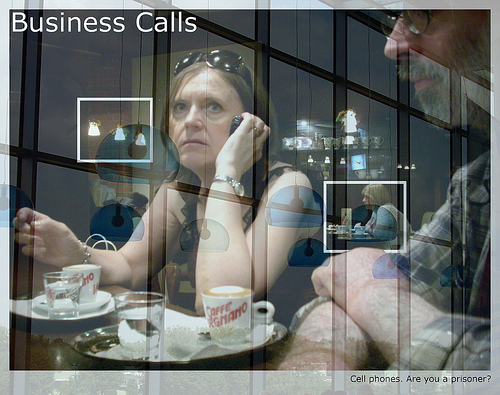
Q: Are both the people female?
A: No, they are both male and female.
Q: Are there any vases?
A: No, there are no vases.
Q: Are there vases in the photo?
A: No, there are no vases.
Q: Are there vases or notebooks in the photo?
A: No, there are no vases or notebooks.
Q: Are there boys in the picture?
A: No, there are no boys.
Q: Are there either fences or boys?
A: No, there are no boys or fences.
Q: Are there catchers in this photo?
A: No, there are no catchers.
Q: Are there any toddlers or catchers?
A: No, there are no catchers or toddlers.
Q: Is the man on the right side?
A: Yes, the man is on the right of the image.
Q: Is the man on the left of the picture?
A: No, the man is on the right of the image.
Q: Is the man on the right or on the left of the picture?
A: The man is on the right of the image.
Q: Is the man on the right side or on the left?
A: The man is on the right of the image.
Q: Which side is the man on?
A: The man is on the right of the image.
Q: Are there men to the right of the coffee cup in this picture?
A: Yes, there is a man to the right of the coffee cup.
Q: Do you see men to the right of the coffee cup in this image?
A: Yes, there is a man to the right of the coffee cup.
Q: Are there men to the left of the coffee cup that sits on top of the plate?
A: No, the man is to the right of the coffee cup.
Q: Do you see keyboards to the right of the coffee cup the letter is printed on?
A: No, there is a man to the right of the coffee cup.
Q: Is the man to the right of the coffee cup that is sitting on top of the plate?
A: Yes, the man is to the right of the coffee cup.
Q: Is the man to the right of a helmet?
A: No, the man is to the right of the coffee cup.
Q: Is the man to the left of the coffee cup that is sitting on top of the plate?
A: No, the man is to the right of the coffee cup.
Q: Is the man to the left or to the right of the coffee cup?
A: The man is to the right of the coffee cup.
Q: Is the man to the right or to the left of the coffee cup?
A: The man is to the right of the coffee cup.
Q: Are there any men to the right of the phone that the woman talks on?
A: Yes, there is a man to the right of the phone.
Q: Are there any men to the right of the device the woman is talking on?
A: Yes, there is a man to the right of the phone.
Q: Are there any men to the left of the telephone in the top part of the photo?
A: No, the man is to the right of the telephone.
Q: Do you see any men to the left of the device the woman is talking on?
A: No, the man is to the right of the telephone.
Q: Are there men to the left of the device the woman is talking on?
A: No, the man is to the right of the telephone.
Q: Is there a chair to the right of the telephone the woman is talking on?
A: No, there is a man to the right of the telephone.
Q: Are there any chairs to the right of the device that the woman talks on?
A: No, there is a man to the right of the telephone.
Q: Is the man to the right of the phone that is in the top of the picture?
A: Yes, the man is to the right of the telephone.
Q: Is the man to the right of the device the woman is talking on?
A: Yes, the man is to the right of the telephone.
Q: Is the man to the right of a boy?
A: No, the man is to the right of the telephone.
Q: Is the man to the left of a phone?
A: No, the man is to the right of a phone.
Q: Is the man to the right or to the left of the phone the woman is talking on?
A: The man is to the right of the telephone.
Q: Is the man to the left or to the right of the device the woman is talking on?
A: The man is to the right of the telephone.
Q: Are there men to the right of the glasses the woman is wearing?
A: Yes, there is a man to the right of the glasses.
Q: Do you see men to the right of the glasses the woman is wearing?
A: Yes, there is a man to the right of the glasses.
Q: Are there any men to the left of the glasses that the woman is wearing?
A: No, the man is to the right of the glasses.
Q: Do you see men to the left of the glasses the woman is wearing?
A: No, the man is to the right of the glasses.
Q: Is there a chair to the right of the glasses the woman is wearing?
A: No, there is a man to the right of the glasses.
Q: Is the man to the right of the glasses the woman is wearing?
A: Yes, the man is to the right of the glasses.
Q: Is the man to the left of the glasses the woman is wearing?
A: No, the man is to the right of the glasses.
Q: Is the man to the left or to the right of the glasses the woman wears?
A: The man is to the right of the glasses.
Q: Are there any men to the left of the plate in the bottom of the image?
A: No, the man is to the right of the plate.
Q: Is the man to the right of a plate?
A: Yes, the man is to the right of a plate.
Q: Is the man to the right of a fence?
A: No, the man is to the right of a plate.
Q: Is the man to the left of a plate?
A: No, the man is to the right of a plate.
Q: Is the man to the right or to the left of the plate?
A: The man is to the right of the plate.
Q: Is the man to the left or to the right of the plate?
A: The man is to the right of the plate.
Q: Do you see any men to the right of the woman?
A: Yes, there is a man to the right of the woman.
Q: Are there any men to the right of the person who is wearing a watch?
A: Yes, there is a man to the right of the woman.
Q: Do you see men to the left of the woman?
A: No, the man is to the right of the woman.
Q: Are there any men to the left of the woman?
A: No, the man is to the right of the woman.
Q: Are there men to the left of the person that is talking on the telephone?
A: No, the man is to the right of the woman.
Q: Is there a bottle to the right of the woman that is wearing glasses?
A: No, there is a man to the right of the woman.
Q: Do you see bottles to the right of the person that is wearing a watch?
A: No, there is a man to the right of the woman.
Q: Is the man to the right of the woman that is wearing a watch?
A: Yes, the man is to the right of the woman.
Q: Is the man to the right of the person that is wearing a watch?
A: Yes, the man is to the right of the woman.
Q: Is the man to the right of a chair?
A: No, the man is to the right of the woman.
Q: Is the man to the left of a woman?
A: No, the man is to the right of a woman.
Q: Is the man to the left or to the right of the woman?
A: The man is to the right of the woman.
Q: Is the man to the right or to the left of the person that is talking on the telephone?
A: The man is to the right of the woman.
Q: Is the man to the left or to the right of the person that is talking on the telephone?
A: The man is to the right of the woman.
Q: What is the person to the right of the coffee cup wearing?
A: The man is wearing glasses.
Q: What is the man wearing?
A: The man is wearing glasses.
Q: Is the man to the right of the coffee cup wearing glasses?
A: Yes, the man is wearing glasses.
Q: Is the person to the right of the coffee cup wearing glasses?
A: Yes, the man is wearing glasses.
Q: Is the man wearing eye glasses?
A: No, the man is wearing glasses.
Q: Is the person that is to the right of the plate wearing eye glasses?
A: No, the man is wearing glasses.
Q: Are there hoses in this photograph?
A: No, there are no hoses.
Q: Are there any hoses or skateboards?
A: No, there are no hoses or skateboards.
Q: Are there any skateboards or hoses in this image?
A: No, there are no hoses or skateboards.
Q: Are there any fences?
A: No, there are no fences.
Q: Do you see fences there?
A: No, there are no fences.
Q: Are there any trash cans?
A: No, there are no trash cans.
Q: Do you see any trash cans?
A: No, there are no trash cans.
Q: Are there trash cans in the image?
A: No, there are no trash cans.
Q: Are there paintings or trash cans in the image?
A: No, there are no trash cans or paintings.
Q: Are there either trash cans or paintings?
A: No, there are no trash cans or paintings.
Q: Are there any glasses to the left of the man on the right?
A: Yes, there are glasses to the left of the man.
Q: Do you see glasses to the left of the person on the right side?
A: Yes, there are glasses to the left of the man.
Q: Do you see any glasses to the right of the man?
A: No, the glasses are to the left of the man.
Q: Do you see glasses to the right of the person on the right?
A: No, the glasses are to the left of the man.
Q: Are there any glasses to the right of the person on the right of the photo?
A: No, the glasses are to the left of the man.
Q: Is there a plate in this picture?
A: Yes, there is a plate.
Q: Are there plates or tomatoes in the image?
A: Yes, there is a plate.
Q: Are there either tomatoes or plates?
A: Yes, there is a plate.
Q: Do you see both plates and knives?
A: No, there is a plate but no knives.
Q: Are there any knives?
A: No, there are no knives.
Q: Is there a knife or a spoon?
A: No, there are no knives or spoons.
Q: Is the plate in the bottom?
A: Yes, the plate is in the bottom of the image.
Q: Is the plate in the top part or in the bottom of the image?
A: The plate is in the bottom of the image.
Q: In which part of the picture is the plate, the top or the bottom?
A: The plate is in the bottom of the image.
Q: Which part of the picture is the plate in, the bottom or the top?
A: The plate is in the bottom of the image.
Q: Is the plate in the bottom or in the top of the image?
A: The plate is in the bottom of the image.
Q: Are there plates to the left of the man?
A: Yes, there is a plate to the left of the man.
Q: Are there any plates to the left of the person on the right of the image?
A: Yes, there is a plate to the left of the man.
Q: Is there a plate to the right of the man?
A: No, the plate is to the left of the man.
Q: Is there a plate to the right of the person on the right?
A: No, the plate is to the left of the man.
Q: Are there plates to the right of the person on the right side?
A: No, the plate is to the left of the man.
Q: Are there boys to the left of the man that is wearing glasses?
A: No, there is a plate to the left of the man.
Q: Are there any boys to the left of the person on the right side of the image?
A: No, there is a plate to the left of the man.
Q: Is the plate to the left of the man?
A: Yes, the plate is to the left of the man.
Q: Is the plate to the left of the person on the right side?
A: Yes, the plate is to the left of the man.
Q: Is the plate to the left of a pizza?
A: No, the plate is to the left of the man.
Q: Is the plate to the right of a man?
A: No, the plate is to the left of a man.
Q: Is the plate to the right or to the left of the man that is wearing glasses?
A: The plate is to the left of the man.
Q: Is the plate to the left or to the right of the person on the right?
A: The plate is to the left of the man.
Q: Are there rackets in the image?
A: No, there are no rackets.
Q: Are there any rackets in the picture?
A: No, there are no rackets.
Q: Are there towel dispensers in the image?
A: No, there are no towel dispensers.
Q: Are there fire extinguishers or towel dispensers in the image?
A: No, there are no towel dispensers or fire extinguishers.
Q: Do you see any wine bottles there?
A: No, there are no wine bottles.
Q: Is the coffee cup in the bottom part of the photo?
A: Yes, the coffee cup is in the bottom of the image.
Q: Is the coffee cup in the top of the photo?
A: No, the coffee cup is in the bottom of the image.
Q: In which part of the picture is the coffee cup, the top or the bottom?
A: The coffee cup is in the bottom of the image.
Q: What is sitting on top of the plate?
A: The coffee cup is sitting on top of the plate.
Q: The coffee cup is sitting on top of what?
A: The coffee cup is sitting on top of the plate.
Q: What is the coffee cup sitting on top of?
A: The coffee cup is sitting on top of the plate.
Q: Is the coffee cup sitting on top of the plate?
A: Yes, the coffee cup is sitting on top of the plate.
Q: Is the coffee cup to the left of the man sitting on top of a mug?
A: No, the coffee cup is sitting on top of the plate.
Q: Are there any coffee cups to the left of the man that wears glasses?
A: Yes, there is a coffee cup to the left of the man.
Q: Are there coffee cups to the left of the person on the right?
A: Yes, there is a coffee cup to the left of the man.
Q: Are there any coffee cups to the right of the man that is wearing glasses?
A: No, the coffee cup is to the left of the man.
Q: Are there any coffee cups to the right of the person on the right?
A: No, the coffee cup is to the left of the man.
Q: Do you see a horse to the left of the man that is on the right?
A: No, there is a coffee cup to the left of the man.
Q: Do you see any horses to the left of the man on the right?
A: No, there is a coffee cup to the left of the man.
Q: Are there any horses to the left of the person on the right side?
A: No, there is a coffee cup to the left of the man.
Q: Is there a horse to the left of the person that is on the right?
A: No, there is a coffee cup to the left of the man.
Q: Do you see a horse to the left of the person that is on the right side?
A: No, there is a coffee cup to the left of the man.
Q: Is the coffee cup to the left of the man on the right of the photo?
A: Yes, the coffee cup is to the left of the man.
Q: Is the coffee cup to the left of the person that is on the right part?
A: Yes, the coffee cup is to the left of the man.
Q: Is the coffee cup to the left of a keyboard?
A: No, the coffee cup is to the left of the man.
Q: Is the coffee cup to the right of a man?
A: No, the coffee cup is to the left of a man.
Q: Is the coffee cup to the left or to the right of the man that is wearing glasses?
A: The coffee cup is to the left of the man.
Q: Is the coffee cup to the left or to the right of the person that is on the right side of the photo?
A: The coffee cup is to the left of the man.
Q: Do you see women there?
A: Yes, there is a woman.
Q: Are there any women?
A: Yes, there is a woman.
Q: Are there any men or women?
A: Yes, there is a woman.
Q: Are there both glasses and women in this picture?
A: Yes, there are both a woman and glasses.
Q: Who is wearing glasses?
A: The woman is wearing glasses.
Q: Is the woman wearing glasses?
A: Yes, the woman is wearing glasses.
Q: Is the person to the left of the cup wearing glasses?
A: Yes, the woman is wearing glasses.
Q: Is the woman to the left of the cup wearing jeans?
A: No, the woman is wearing glasses.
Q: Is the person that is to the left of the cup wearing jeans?
A: No, the woman is wearing glasses.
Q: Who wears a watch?
A: The woman wears a watch.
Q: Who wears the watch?
A: The woman wears a watch.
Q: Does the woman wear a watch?
A: Yes, the woman wears a watch.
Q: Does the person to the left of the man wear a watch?
A: Yes, the woman wears a watch.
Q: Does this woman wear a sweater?
A: No, the woman wears a watch.